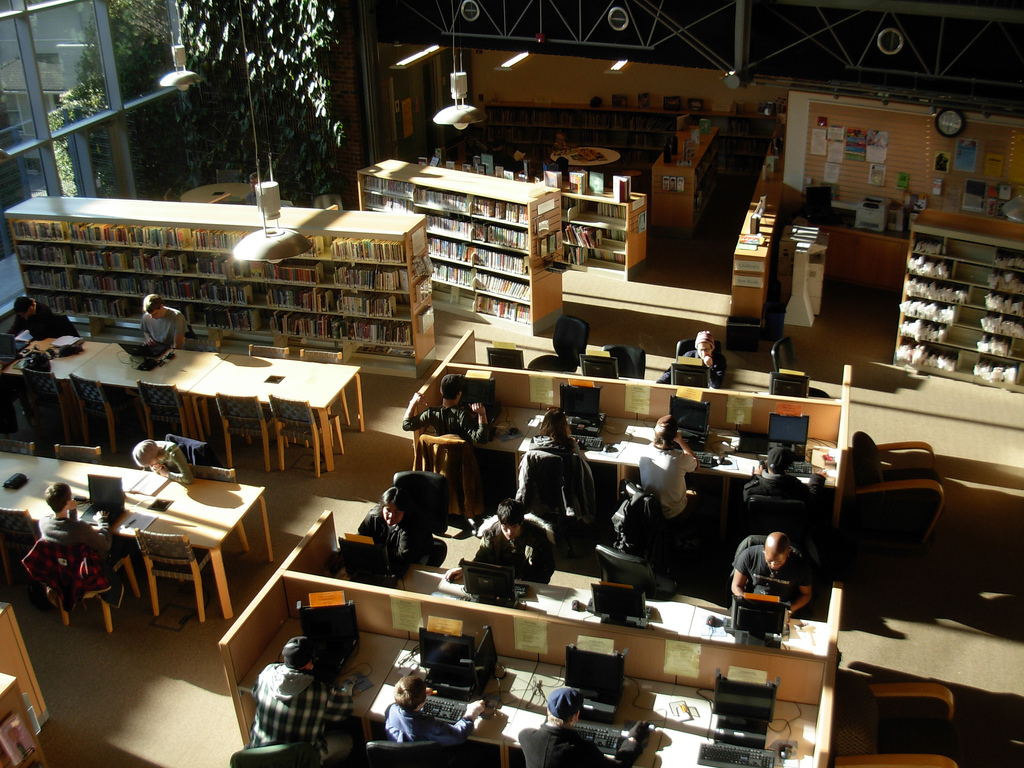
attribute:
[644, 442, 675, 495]
shirt — beige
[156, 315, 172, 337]
shirt — gray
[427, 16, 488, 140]
ceiling fixture — silver, pendant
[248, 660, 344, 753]
shirt — plaid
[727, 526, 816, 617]
person — bald